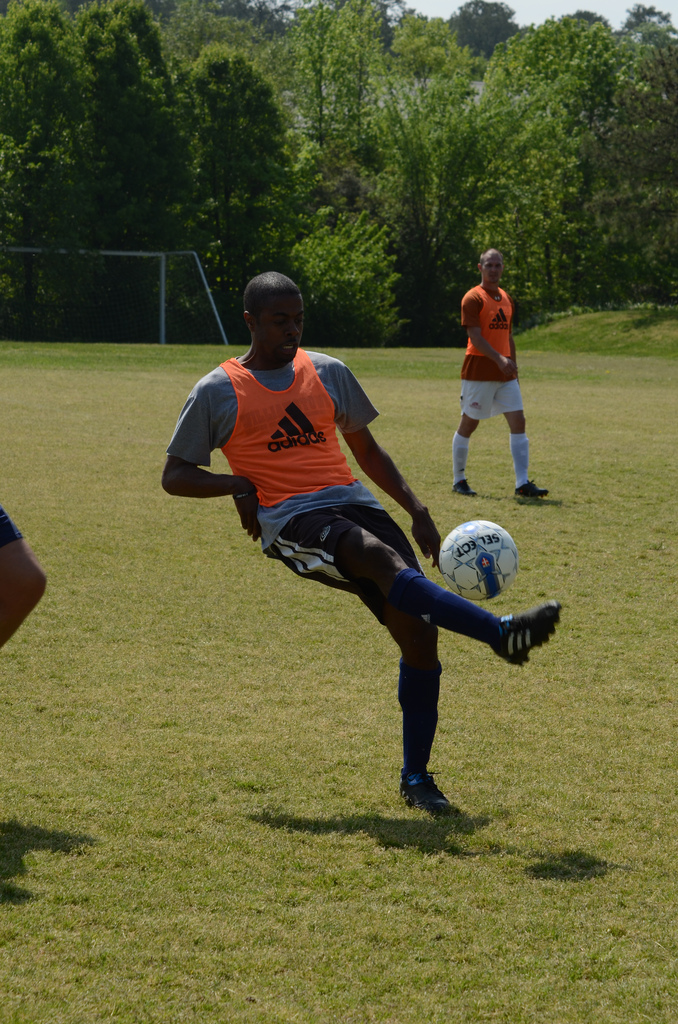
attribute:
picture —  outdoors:
[10, 78, 633, 859]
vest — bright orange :
[442, 253, 555, 411]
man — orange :
[213, 288, 561, 765]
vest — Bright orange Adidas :
[231, 368, 366, 499]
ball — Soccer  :
[431, 517, 561, 617]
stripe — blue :
[431, 517, 561, 617]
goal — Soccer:
[5, 238, 241, 351]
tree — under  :
[5, 21, 241, 352]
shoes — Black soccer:
[369, 549, 605, 820]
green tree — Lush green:
[525, 10, 631, 120]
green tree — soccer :
[440, 54, 585, 324]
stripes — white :
[506, 622, 547, 660]